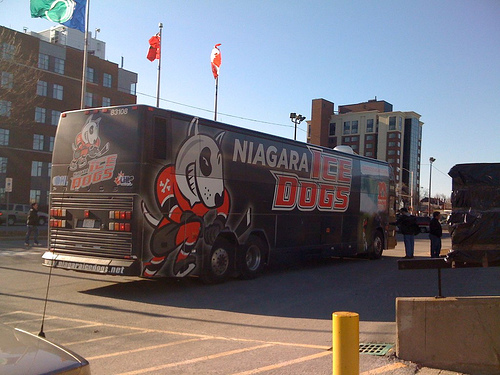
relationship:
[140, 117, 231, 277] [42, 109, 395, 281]
mascot on bus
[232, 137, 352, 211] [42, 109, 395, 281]
writting on bus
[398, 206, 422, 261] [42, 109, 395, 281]
man waiting for bus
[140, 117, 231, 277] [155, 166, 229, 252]
mascot wearing a uniform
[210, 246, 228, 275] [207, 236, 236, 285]
silver hub caps on wheels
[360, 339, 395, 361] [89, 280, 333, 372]
drain on street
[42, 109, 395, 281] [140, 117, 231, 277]
bus has decals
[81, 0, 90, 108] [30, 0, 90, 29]
poles have flags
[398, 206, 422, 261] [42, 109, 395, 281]
people by bus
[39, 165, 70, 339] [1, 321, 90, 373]
an antenna on car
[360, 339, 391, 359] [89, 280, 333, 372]
grate on street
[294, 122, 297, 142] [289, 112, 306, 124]
pole has a lights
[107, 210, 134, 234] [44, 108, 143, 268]
tail lights are on back of the bus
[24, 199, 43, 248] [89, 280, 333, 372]
man crossing street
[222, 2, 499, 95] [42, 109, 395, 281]
blue sky over bus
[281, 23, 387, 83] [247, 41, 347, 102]
clouds in sky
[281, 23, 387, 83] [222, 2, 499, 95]
clouds in blue sky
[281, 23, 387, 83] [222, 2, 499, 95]
clouds in sky